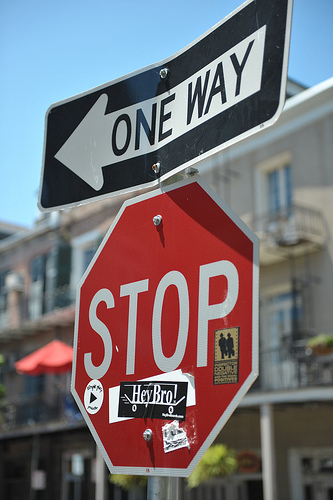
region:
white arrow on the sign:
[16, 28, 271, 196]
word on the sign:
[105, 86, 189, 160]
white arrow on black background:
[41, 22, 272, 195]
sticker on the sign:
[118, 365, 192, 430]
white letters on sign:
[89, 258, 242, 364]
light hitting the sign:
[96, 216, 189, 275]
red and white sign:
[95, 255, 242, 376]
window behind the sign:
[251, 154, 306, 220]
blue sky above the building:
[12, 16, 106, 65]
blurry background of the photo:
[0, 248, 74, 311]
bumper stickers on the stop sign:
[84, 362, 223, 454]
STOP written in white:
[91, 256, 245, 372]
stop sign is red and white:
[59, 191, 269, 481]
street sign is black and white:
[23, 0, 324, 209]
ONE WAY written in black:
[108, 37, 269, 155]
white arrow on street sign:
[52, 18, 288, 186]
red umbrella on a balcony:
[15, 339, 76, 417]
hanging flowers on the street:
[179, 435, 244, 488]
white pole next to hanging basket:
[258, 404, 292, 497]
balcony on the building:
[233, 195, 331, 267]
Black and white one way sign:
[0, 0, 330, 215]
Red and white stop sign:
[59, 170, 288, 481]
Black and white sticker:
[117, 377, 189, 422]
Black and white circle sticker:
[80, 375, 110, 418]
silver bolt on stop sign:
[133, 420, 158, 444]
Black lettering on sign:
[109, 37, 275, 160]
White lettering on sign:
[77, 258, 246, 386]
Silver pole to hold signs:
[134, 470, 183, 499]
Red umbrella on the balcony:
[10, 334, 95, 382]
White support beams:
[255, 405, 287, 498]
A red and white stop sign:
[66, 174, 263, 480]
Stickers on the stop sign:
[79, 323, 241, 454]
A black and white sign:
[33, 1, 294, 215]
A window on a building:
[250, 149, 296, 225]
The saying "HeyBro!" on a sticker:
[129, 380, 183, 412]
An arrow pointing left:
[48, 18, 267, 193]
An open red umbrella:
[9, 338, 79, 378]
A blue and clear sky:
[1, 1, 331, 231]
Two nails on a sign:
[149, 64, 172, 177]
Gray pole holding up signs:
[144, 473, 171, 498]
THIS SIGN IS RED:
[58, 174, 275, 487]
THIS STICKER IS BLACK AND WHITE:
[112, 380, 195, 422]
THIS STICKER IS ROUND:
[69, 376, 109, 418]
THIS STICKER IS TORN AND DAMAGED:
[155, 416, 202, 454]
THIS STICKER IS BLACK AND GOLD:
[202, 321, 257, 399]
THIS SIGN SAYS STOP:
[64, 180, 263, 489]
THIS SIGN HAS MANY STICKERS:
[71, 171, 266, 477]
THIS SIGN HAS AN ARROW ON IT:
[27, 0, 295, 217]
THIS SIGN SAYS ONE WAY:
[33, 0, 289, 215]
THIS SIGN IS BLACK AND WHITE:
[34, 0, 298, 215]